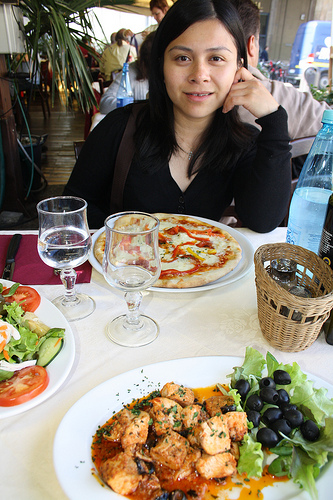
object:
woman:
[61, 0, 293, 231]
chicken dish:
[91, 371, 255, 498]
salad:
[215, 340, 331, 497]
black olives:
[217, 365, 324, 450]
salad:
[2, 284, 48, 390]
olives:
[233, 369, 331, 455]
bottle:
[283, 99, 331, 242]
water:
[284, 185, 331, 216]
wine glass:
[98, 209, 168, 350]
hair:
[111, 1, 276, 196]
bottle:
[116, 63, 134, 108]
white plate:
[239, 230, 254, 280]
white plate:
[165, 288, 218, 296]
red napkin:
[1, 234, 91, 284]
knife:
[1, 231, 21, 279]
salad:
[1, 322, 60, 374]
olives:
[270, 368, 293, 383]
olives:
[259, 372, 274, 390]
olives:
[236, 373, 247, 395]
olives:
[257, 385, 277, 402]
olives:
[248, 390, 260, 408]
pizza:
[94, 212, 239, 287]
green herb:
[114, 368, 161, 407]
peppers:
[169, 224, 201, 262]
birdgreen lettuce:
[4, 305, 60, 365]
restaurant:
[1, 0, 332, 499]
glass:
[90, 211, 170, 351]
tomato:
[1, 285, 39, 314]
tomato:
[0, 365, 48, 405]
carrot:
[0, 341, 11, 361]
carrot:
[0, 324, 8, 340]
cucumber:
[36, 333, 64, 366]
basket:
[252, 235, 332, 361]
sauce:
[100, 437, 120, 452]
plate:
[0, 274, 78, 420]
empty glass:
[102, 210, 160, 347]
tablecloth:
[6, 221, 329, 497]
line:
[78, 340, 121, 369]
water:
[30, 221, 98, 270]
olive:
[272, 370, 291, 386]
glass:
[33, 194, 96, 321]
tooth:
[184, 91, 206, 97]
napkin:
[12, 239, 94, 288]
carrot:
[51, 330, 63, 345]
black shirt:
[54, 93, 295, 237]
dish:
[104, 197, 260, 298]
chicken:
[103, 377, 246, 493]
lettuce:
[250, 365, 308, 401]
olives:
[235, 383, 297, 441]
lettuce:
[232, 360, 285, 459]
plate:
[89, 211, 253, 295]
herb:
[238, 348, 332, 480]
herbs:
[225, 347, 331, 498]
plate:
[45, 342, 323, 492]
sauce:
[92, 383, 249, 499]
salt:
[270, 256, 300, 302]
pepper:
[282, 283, 317, 320]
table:
[6, 219, 322, 498]